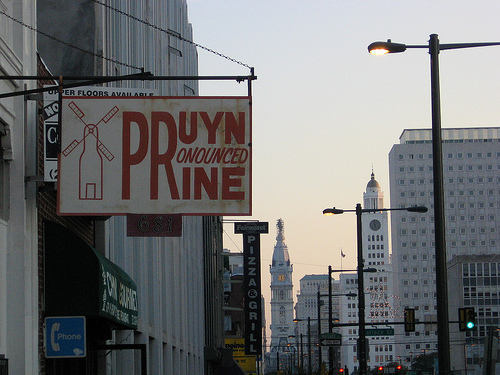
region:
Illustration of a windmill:
[62, 100, 119, 202]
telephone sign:
[43, 316, 85, 356]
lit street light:
[367, 39, 405, 54]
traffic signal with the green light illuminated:
[458, 305, 475, 332]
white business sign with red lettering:
[57, 94, 252, 216]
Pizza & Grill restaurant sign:
[235, 222, 268, 357]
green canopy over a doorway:
[45, 222, 137, 327]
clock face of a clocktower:
[368, 218, 380, 231]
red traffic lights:
[378, 363, 404, 370]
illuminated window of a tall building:
[277, 273, 285, 280]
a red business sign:
[55, 97, 252, 217]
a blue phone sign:
[40, 315, 87, 357]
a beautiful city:
[266, 124, 498, 374]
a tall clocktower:
[355, 163, 395, 371]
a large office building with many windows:
[387, 122, 497, 352]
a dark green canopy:
[40, 221, 141, 322]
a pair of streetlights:
[398, 302, 483, 333]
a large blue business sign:
[233, 218, 270, 353]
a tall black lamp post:
[365, 30, 497, 371]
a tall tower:
[266, 216, 297, 373]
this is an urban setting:
[34, 16, 496, 355]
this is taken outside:
[51, 31, 473, 321]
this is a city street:
[45, 45, 496, 341]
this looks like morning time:
[30, 47, 466, 328]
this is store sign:
[60, 73, 310, 238]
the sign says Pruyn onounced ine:
[33, 67, 376, 272]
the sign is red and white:
[38, 76, 329, 294]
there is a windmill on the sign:
[53, 90, 128, 201]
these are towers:
[260, 150, 406, 325]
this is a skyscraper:
[383, 120, 498, 230]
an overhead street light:
[364, 38, 429, 56]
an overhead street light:
[319, 204, 354, 216]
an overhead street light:
[362, 204, 429, 214]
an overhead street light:
[330, 267, 378, 274]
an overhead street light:
[321, 292, 358, 297]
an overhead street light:
[291, 316, 304, 323]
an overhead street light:
[311, 318, 339, 322]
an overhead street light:
[286, 333, 297, 339]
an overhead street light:
[285, 341, 297, 347]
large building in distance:
[267, 216, 297, 373]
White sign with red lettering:
[53, 90, 258, 221]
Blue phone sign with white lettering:
[38, 311, 90, 363]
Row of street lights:
[283, 31, 498, 372]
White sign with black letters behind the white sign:
[37, 81, 167, 186]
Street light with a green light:
[455, 303, 480, 337]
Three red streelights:
[332, 362, 409, 374]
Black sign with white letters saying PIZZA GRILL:
[230, 218, 275, 360]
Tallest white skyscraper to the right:
[382, 121, 497, 373]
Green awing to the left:
[75, 241, 143, 336]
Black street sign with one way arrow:
[315, 329, 345, 349]